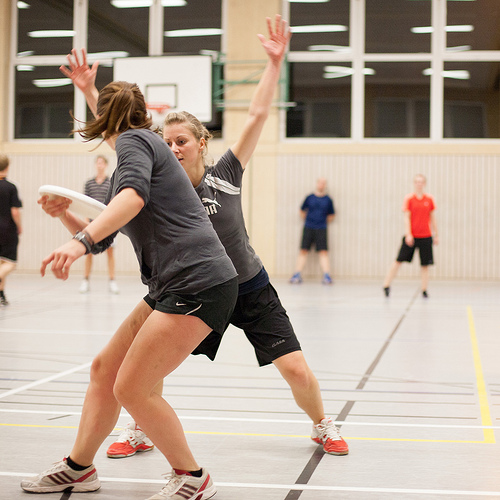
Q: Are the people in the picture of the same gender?
A: Yes, all the people are female.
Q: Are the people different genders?
A: No, all the people are female.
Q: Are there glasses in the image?
A: No, there are no glasses.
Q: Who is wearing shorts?
A: The girl is wearing shorts.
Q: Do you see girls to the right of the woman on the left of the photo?
A: Yes, there is a girl to the right of the woman.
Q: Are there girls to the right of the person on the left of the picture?
A: Yes, there is a girl to the right of the woman.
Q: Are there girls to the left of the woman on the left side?
A: No, the girl is to the right of the woman.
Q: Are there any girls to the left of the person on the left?
A: No, the girl is to the right of the woman.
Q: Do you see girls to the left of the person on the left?
A: No, the girl is to the right of the woman.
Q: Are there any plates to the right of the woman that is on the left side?
A: No, there is a girl to the right of the woman.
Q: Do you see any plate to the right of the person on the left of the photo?
A: No, there is a girl to the right of the woman.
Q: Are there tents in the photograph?
A: No, there are no tents.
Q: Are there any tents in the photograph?
A: No, there are no tents.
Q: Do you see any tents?
A: No, there are no tents.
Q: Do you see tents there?
A: No, there are no tents.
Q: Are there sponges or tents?
A: No, there are no tents or sponges.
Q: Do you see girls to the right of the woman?
A: Yes, there is a girl to the right of the woman.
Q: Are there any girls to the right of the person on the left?
A: Yes, there is a girl to the right of the woman.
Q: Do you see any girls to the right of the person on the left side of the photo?
A: Yes, there is a girl to the right of the woman.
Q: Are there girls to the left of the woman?
A: No, the girl is to the right of the woman.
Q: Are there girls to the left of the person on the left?
A: No, the girl is to the right of the woman.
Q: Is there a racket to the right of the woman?
A: No, there is a girl to the right of the woman.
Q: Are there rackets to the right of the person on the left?
A: No, there is a girl to the right of the woman.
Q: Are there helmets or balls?
A: No, there are no balls or helmets.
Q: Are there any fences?
A: No, there are no fences.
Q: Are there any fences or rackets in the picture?
A: No, there are no fences or rackets.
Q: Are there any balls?
A: No, there are no balls.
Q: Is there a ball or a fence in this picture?
A: No, there are no balls or fences.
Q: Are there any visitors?
A: No, there are no visitors.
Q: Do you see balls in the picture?
A: No, there are no balls.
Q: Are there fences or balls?
A: No, there are no balls or fences.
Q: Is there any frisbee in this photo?
A: Yes, there is a frisbee.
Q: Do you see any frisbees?
A: Yes, there is a frisbee.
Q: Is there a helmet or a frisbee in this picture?
A: Yes, there is a frisbee.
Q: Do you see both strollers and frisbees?
A: No, there is a frisbee but no strollers.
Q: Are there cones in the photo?
A: No, there are no cones.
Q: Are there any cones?
A: No, there are no cones.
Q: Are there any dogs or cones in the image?
A: No, there are no cones or dogs.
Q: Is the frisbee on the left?
A: Yes, the frisbee is on the left of the image.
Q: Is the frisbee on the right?
A: No, the frisbee is on the left of the image.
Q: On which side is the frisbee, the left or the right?
A: The frisbee is on the left of the image.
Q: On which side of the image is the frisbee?
A: The frisbee is on the left of the image.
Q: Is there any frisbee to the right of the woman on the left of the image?
A: Yes, there is a frisbee to the right of the woman.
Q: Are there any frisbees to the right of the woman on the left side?
A: Yes, there is a frisbee to the right of the woman.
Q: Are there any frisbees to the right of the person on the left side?
A: Yes, there is a frisbee to the right of the woman.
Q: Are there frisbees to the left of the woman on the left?
A: No, the frisbee is to the right of the woman.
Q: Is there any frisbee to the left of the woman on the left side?
A: No, the frisbee is to the right of the woman.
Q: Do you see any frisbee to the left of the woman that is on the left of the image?
A: No, the frisbee is to the right of the woman.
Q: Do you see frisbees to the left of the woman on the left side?
A: No, the frisbee is to the right of the woman.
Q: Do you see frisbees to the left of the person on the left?
A: No, the frisbee is to the right of the woman.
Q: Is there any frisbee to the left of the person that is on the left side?
A: No, the frisbee is to the right of the woman.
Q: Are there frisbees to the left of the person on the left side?
A: No, the frisbee is to the right of the woman.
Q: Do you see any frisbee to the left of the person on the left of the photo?
A: No, the frisbee is to the right of the woman.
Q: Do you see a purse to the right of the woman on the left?
A: No, there is a frisbee to the right of the woman.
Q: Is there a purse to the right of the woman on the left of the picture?
A: No, there is a frisbee to the right of the woman.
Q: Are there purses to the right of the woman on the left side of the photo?
A: No, there is a frisbee to the right of the woman.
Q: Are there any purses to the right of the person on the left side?
A: No, there is a frisbee to the right of the woman.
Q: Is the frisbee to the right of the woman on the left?
A: Yes, the frisbee is to the right of the woman.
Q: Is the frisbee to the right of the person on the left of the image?
A: Yes, the frisbee is to the right of the woman.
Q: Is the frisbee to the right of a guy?
A: No, the frisbee is to the right of the woman.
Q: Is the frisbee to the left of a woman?
A: No, the frisbee is to the right of a woman.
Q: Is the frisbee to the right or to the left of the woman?
A: The frisbee is to the right of the woman.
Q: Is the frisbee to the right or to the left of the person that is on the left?
A: The frisbee is to the right of the woman.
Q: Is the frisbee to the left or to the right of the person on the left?
A: The frisbee is to the right of the woman.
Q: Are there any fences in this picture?
A: No, there are no fences.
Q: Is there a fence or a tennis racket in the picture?
A: No, there are no fences or rackets.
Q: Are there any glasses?
A: No, there are no glasses.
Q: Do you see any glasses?
A: No, there are no glasses.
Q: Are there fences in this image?
A: No, there are no fences.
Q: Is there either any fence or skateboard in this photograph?
A: No, there are no fences or skateboards.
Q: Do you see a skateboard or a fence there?
A: No, there are no fences or skateboards.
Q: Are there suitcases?
A: No, there are no suitcases.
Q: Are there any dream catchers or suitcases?
A: No, there are no suitcases or dream catchers.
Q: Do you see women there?
A: Yes, there is a woman.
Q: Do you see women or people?
A: Yes, there is a woman.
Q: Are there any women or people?
A: Yes, there is a woman.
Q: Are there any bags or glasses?
A: No, there are no glasses or bags.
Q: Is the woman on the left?
A: Yes, the woman is on the left of the image.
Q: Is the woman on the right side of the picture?
A: No, the woman is on the left of the image.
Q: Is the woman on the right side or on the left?
A: The woman is on the left of the image.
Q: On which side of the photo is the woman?
A: The woman is on the left of the image.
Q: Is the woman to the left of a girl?
A: Yes, the woman is to the left of a girl.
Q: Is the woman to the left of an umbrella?
A: No, the woman is to the left of a girl.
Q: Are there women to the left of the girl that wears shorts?
A: Yes, there is a woman to the left of the girl.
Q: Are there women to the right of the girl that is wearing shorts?
A: No, the woman is to the left of the girl.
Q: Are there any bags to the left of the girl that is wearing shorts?
A: No, there is a woman to the left of the girl.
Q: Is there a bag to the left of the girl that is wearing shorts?
A: No, there is a woman to the left of the girl.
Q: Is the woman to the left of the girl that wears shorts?
A: Yes, the woman is to the left of the girl.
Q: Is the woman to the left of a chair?
A: No, the woman is to the left of the girl.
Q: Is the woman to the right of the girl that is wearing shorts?
A: No, the woman is to the left of the girl.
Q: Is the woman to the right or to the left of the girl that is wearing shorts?
A: The woman is to the left of the girl.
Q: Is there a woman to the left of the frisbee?
A: Yes, there is a woman to the left of the frisbee.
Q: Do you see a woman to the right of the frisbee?
A: No, the woman is to the left of the frisbee.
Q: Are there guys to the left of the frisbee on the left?
A: No, there is a woman to the left of the frisbee.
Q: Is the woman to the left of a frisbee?
A: Yes, the woman is to the left of a frisbee.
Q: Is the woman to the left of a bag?
A: No, the woman is to the left of a frisbee.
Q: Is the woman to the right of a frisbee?
A: No, the woman is to the left of a frisbee.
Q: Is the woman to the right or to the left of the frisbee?
A: The woman is to the left of the frisbee.